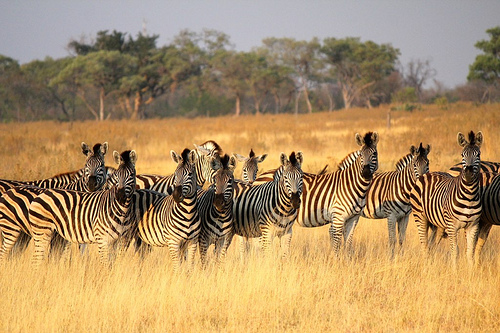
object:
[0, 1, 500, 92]
sky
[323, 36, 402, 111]
leaves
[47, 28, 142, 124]
tree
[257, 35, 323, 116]
trees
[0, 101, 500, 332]
field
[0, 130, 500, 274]
herd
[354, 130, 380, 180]
head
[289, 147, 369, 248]
stripes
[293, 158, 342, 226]
torso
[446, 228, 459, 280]
feet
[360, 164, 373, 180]
nose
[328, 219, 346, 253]
legs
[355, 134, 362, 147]
ear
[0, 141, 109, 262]
zebras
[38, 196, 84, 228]
stripes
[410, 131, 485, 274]
zebra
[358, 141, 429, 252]
zebra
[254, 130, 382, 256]
zebra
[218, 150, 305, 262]
zebra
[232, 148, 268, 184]
zebra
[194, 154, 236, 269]
zebra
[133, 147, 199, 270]
zebra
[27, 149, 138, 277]
zebra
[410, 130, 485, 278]
animals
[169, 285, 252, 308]
grass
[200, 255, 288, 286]
ground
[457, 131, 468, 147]
ears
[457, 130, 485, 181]
head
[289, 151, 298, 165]
hair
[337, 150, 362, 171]
hair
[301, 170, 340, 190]
back